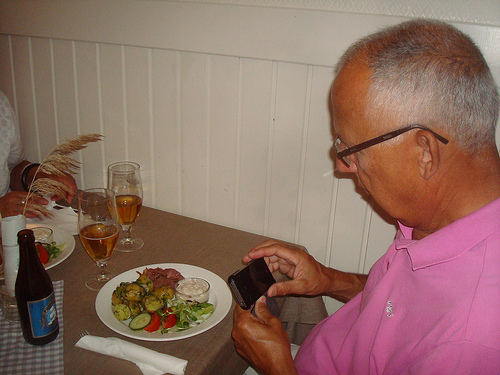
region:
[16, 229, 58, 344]
a beer bottle with a blue label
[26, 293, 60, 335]
blue label on the bottle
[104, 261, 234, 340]
round white plate with a salad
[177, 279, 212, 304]
small cup of salad dressing on plate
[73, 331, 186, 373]
utensils rolled in a white napkin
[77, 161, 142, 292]
two glasses with beer in them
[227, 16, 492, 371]
a man holding a small digital camera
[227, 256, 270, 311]
a digital camera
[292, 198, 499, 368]
the man's pink polo shirt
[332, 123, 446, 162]
the man's eye glasses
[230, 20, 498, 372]
Grey-haired man with glasses wearing pink shirt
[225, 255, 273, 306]
Screen of a black cell phone held horizontally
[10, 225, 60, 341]
Bottle of beer with blue label on front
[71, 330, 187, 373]
Rolled up white napkin on table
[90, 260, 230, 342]
White plate with salad and dressing in glass bowl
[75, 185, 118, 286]
Slender glass of golden-colored beer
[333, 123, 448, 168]
Pair of black glasses with rectangular lenses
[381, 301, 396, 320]
White embroidered animal logo on shirt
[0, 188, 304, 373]
Square table with taupe table cloth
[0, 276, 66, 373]
Light grey and white checked place mat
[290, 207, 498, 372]
the man's shirt is pink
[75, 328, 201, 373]
utensils wrapped in a napkin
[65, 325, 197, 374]
a napkin wrapped around utensils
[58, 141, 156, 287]
two beer glasses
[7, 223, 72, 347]
this is a bottle of beer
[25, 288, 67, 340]
the bottle has a blue label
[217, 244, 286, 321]
this is a touch screen phone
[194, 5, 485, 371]
the man is taking a picture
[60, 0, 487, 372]
the is snapping a photo of his food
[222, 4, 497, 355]
he is using his phone to take a picture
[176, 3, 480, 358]
the man is looking at a phone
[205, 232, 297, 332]
the device is black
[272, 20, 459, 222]
the man is wearing glasses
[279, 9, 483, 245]
the man is looking down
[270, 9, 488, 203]
the man`s hair is grey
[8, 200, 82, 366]
a bottle on the table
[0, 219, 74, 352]
the bottle is dark brown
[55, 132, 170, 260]
two glasses on the table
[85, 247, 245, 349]
a plate of food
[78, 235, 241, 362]
the plate is white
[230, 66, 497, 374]
Man sitting by the table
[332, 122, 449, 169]
Glasses on the man's face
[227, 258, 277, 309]
Cellphone in the man's hands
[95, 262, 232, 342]
White plate on the table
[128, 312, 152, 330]
Cucumber slice on the plate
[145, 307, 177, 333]
Tomato slices on the plate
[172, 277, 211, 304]
Salad dressing on the plate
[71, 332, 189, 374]
Napkin on the table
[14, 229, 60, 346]
Bottle on the table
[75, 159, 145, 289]
Glasses on the table